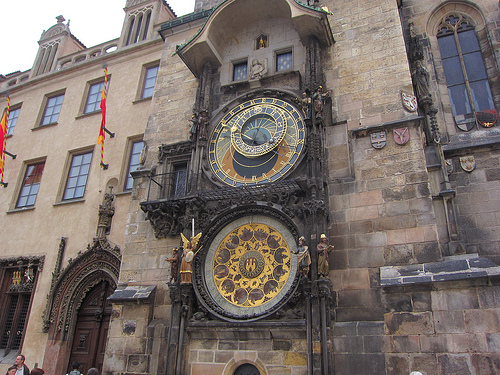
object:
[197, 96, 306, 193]
clock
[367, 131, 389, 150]
shield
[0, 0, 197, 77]
sky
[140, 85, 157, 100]
window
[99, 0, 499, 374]
brick wall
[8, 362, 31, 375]
jacket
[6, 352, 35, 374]
man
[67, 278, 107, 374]
door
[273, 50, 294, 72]
window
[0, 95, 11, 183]
flag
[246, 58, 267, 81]
statue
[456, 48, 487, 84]
window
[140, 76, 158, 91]
window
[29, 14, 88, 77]
top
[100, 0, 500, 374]
building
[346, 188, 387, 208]
stone block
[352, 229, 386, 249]
stone block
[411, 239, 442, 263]
stone block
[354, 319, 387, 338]
stone block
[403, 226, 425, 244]
stone block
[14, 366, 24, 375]
shirt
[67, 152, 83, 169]
windows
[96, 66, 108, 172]
flag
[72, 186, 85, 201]
window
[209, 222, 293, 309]
ornate medallion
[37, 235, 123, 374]
archway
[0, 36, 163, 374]
wall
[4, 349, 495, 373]
street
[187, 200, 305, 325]
shield